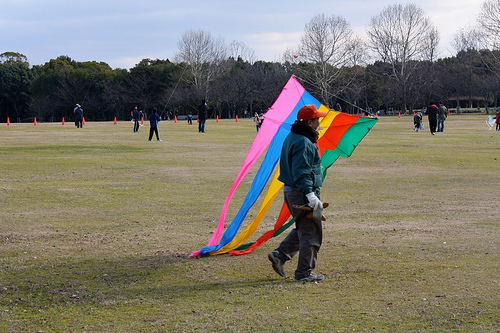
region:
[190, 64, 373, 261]
Man with colorful kite.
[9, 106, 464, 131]
Orange cones in the background.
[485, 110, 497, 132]
Person with kite in the background.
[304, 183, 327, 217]
Man with white gloves.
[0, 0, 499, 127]
Trees in the background.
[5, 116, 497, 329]
Large grassy field.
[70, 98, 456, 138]
People in the background flying kites.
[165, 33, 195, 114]
String being held for flying.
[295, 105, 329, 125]
Red ball cap on man.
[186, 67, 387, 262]
Flag falling on the ground.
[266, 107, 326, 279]
A guy holding a large kite.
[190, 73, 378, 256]
A large multi colored kite.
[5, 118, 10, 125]
An orange traffic cone.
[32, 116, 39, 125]
An orange traffic cone.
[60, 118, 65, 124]
An orange traffic cone.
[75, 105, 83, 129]
A guy in the background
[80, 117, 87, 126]
An orange traffic cone.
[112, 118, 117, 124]
An orange traffic cone.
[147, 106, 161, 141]
A child flying a kite.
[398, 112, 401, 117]
An orange traffic cone.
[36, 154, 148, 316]
Grass is green color.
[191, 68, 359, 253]
Man is carrying one kite in hand.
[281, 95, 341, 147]
Man is wearing red cap.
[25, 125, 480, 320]
Grasses are found in patches.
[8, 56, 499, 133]
Trees are green color.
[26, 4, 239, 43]
Sky is blue color.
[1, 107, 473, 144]
Orange cone is kept in ground.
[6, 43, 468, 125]
Trees are behind the people.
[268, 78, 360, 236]
Kite is multicolor.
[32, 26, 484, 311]
Day time picture.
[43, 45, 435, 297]
picture taken outside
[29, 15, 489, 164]
picture taken during the day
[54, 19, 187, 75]
the sky is blue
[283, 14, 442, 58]
the trees are missing leaves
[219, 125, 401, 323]
the man is holding a large kite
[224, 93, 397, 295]
the kite has many colors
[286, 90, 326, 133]
the man is wearing a hat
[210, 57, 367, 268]
the kite has purple, blue, yellow, red and green colors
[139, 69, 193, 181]
a man is holding a kite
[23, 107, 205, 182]
orange cones are on the ground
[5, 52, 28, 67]
a tree in a distance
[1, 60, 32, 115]
a tree in a distance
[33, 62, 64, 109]
a tree in a distance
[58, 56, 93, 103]
a tree in a distance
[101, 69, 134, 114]
a tree in a distance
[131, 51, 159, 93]
a tree in a distance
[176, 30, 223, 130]
a tree in a distance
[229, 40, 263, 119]
a tree in a distance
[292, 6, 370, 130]
a tree in a distance